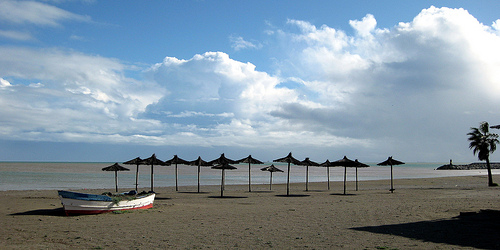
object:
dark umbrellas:
[102, 162, 130, 192]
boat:
[57, 190, 155, 216]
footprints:
[218, 218, 303, 244]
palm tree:
[466, 121, 499, 187]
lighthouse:
[449, 159, 452, 165]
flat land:
[436, 162, 496, 170]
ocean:
[0, 162, 98, 190]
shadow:
[347, 208, 498, 249]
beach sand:
[1, 215, 497, 247]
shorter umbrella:
[318, 159, 336, 190]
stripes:
[65, 201, 154, 207]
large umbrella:
[123, 157, 150, 191]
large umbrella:
[164, 155, 191, 191]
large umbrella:
[140, 153, 167, 192]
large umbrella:
[189, 156, 216, 193]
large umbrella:
[297, 157, 320, 191]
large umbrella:
[211, 161, 237, 197]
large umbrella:
[208, 153, 239, 190]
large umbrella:
[237, 155, 265, 192]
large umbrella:
[260, 164, 284, 190]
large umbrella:
[273, 152, 302, 196]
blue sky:
[4, 3, 498, 115]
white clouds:
[123, 30, 458, 133]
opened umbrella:
[347, 159, 370, 191]